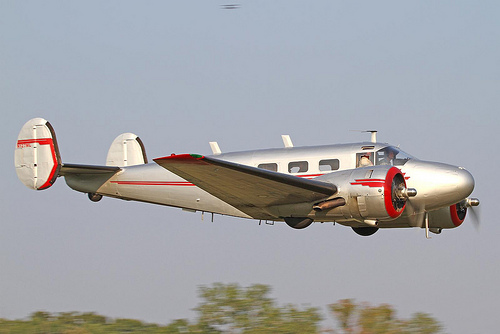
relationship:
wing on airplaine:
[152, 153, 338, 219] [13, 117, 478, 237]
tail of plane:
[13, 117, 62, 190] [10, 106, 486, 248]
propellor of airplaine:
[396, 188, 416, 200] [13, 117, 478, 237]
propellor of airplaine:
[393, 161, 427, 231] [13, 117, 478, 237]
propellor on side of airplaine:
[396, 188, 416, 200] [13, 117, 478, 237]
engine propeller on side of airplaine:
[461, 195, 482, 224] [13, 117, 478, 237]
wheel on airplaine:
[354, 225, 379, 235] [13, 117, 478, 237]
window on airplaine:
[353, 149, 373, 169] [13, 117, 478, 237]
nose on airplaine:
[368, 142, 495, 236] [13, 117, 478, 237]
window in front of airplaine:
[318, 157, 340, 172] [13, 117, 478, 237]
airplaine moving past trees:
[13, 117, 478, 237] [0, 278, 442, 333]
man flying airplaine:
[354, 150, 373, 169] [13, 117, 478, 237]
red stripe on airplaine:
[110, 181, 193, 187] [13, 117, 478, 237]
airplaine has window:
[13, 117, 478, 237] [354, 143, 409, 164]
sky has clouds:
[194, 34, 380, 78] [135, 44, 251, 126]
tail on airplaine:
[13, 117, 62, 190] [13, 117, 478, 237]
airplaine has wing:
[13, 117, 478, 237] [152, 153, 338, 219]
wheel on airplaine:
[282, 214, 314, 228] [13, 117, 478, 237]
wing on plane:
[151, 139, 341, 234] [0, 86, 495, 238]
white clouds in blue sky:
[403, 42, 464, 107] [0, 1, 498, 332]